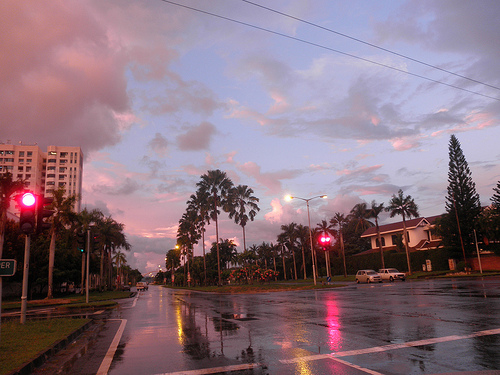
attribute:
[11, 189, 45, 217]
light — red, bright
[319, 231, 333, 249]
light — red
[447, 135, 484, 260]
tree — tall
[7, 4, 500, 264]
sky — blue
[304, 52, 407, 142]
clouds — white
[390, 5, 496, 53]
clouds — white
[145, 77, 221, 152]
clouds — white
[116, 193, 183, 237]
clouds — white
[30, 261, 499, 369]
street — wet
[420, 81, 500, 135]
clouds — white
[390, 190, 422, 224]
tree — green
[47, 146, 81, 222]
building — tall, white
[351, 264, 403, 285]
cars — parked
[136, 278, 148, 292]
car — turning, waiting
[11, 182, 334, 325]
lights — red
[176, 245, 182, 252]
light — yellow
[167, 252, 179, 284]
light — green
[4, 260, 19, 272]
sign — green